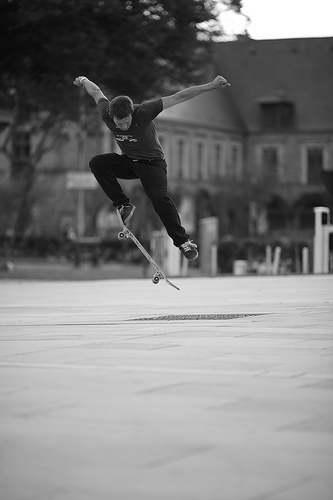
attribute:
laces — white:
[178, 242, 194, 253]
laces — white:
[115, 202, 126, 214]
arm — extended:
[71, 70, 232, 111]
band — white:
[78, 74, 87, 84]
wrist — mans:
[76, 74, 87, 90]